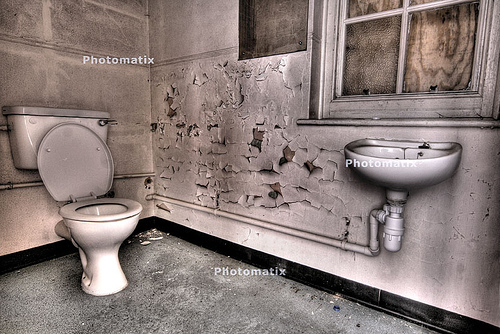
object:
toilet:
[1, 104, 143, 297]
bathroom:
[0, 0, 500, 334]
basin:
[342, 137, 462, 190]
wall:
[150, 1, 499, 329]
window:
[323, 1, 495, 117]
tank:
[3, 106, 111, 169]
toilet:
[36, 120, 142, 296]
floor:
[1, 226, 439, 333]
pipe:
[144, 193, 381, 259]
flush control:
[98, 119, 119, 126]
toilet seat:
[58, 196, 143, 222]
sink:
[343, 137, 462, 190]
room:
[0, 0, 499, 333]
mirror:
[238, 1, 307, 60]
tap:
[418, 142, 430, 149]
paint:
[156, 60, 345, 216]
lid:
[36, 121, 115, 203]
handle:
[99, 119, 117, 127]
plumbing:
[145, 192, 383, 258]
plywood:
[342, 0, 477, 95]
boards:
[342, 1, 477, 94]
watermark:
[82, 55, 154, 66]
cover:
[1, 105, 111, 119]